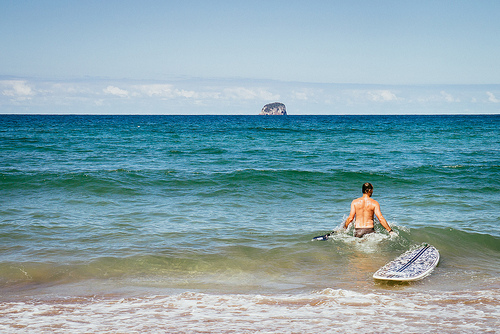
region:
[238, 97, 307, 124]
single large rock out in ocean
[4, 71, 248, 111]
clouds in sky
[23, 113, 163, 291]
clam ocean waters depth color variations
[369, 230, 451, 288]
white surf board with blue decorations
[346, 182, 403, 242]
man walking out in to water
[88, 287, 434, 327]
waves breaking at the shore line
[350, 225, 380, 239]
brown swim trunks on a man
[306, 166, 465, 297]
man going out to surf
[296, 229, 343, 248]
object floating in ocean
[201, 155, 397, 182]
waves in ocean on calm day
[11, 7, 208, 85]
this is the sky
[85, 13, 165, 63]
the sky is blue in color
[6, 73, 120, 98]
the sky has some clouds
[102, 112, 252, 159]
this is an ocean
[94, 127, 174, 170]
the water is blue in color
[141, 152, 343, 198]
the water is wavy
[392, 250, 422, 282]
this is a surfboard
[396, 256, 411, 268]
the surfboard is wooden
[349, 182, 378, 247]
man on the water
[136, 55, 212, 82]
the sky is clear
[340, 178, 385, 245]
this is a man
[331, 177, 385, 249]
the man in water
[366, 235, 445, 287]
a surf board is beside the man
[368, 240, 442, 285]
the surf board is white and black in color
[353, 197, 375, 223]
the man is bare chested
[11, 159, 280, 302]
the waves are small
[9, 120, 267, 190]
the water is green in color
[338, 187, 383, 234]
the man is wet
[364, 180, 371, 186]
the man is bald headed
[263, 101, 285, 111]
this is an isand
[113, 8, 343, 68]
this is the sky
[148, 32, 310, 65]
the sky is blue in color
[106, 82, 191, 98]
these are clouds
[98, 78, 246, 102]
the clouds are white in color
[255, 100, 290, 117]
this is a rock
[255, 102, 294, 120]
the rock is on the sea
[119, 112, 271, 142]
this is water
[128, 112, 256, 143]
the water is blue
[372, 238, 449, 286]
this is a skating board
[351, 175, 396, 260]
the man is in the water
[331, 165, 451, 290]
man and surfboard in water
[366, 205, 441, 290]
board with black stripes on spotted pattern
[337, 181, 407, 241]
man extending hand into water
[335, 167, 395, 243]
back of bare-chested man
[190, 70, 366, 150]
compact island on horizon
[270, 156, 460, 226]
small wave in front of man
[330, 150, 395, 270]
surfer in water up to hips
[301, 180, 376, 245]
silver and blue object floating next to man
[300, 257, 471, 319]
sea foam in front of surfboard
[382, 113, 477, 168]
deep blue and turquoise water of ocean